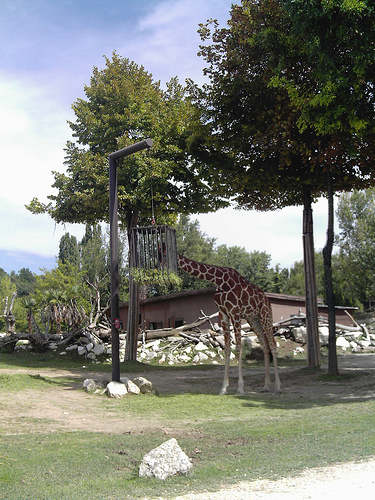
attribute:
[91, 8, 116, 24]
sky — blue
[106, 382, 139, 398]
rocks — gray, white, grey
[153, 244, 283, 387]
giraffe — eating, tall, brown, white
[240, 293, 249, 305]
spots — brown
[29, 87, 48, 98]
clouds — white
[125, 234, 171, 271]
feeder — hanging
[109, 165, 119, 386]
pole — grey, metal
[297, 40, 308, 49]
leaves — green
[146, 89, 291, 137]
trees — tall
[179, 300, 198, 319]
building — brown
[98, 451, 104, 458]
grass — green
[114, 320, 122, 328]
item — red